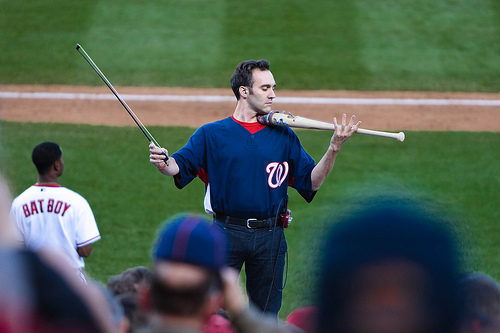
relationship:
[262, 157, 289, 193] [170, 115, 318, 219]
w on blue shirt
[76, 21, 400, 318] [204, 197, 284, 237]
man wearing belt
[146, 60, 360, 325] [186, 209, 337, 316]
man wearing jeans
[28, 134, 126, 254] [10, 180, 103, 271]
boy wearing jersey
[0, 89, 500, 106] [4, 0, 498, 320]
line marking field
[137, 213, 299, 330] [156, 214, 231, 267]
man wearing blue hat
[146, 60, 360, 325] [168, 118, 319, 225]
man wearing shirt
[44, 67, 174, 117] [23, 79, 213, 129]
line in dirt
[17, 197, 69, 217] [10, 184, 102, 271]
batboy written on jersey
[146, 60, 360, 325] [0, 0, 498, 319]
man in baseball park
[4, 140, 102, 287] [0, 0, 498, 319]
boy in baseball park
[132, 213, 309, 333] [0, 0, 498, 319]
man in baseball park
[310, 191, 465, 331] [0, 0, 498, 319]
person in baseball park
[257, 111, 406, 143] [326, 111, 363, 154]
baseball bat in hand